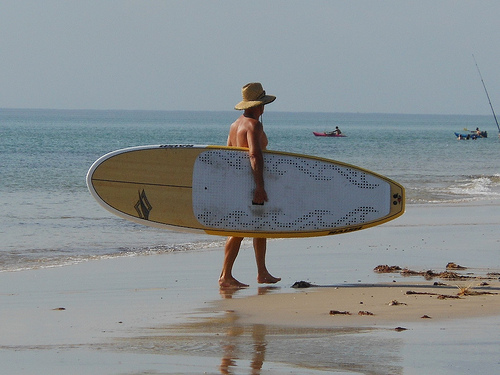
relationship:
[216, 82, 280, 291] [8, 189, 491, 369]
man on beach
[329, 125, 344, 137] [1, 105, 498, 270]
man on water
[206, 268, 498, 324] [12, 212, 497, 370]
sand on beach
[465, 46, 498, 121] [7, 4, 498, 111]
pole in sky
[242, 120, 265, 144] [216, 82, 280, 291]
shoulder on man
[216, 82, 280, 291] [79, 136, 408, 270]
man with surfboard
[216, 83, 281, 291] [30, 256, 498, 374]
man on beach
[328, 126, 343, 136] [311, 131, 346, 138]
woman on jet ski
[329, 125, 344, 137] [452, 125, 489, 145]
man on boat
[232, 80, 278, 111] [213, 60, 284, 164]
straw hat on man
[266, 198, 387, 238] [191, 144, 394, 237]
design on surf board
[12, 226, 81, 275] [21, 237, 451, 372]
ocean on beach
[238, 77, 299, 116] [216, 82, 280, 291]
head on man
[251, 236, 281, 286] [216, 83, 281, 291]
leg on man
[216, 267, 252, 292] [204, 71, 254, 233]
foot of man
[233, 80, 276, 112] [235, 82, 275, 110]
hat of straw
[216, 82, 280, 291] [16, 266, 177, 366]
man on beach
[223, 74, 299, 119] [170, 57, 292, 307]
hat on man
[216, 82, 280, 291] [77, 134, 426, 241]
man on surf board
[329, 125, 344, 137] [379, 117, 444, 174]
man in water